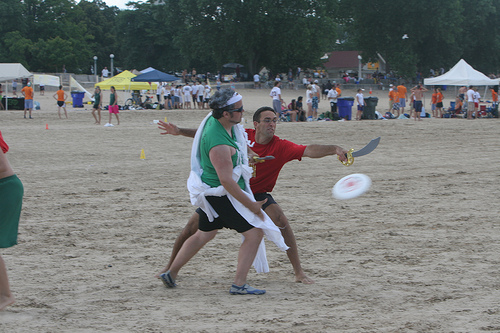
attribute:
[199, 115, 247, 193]
shirt — green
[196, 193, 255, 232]
shorts — black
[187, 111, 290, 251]
toilet paper — white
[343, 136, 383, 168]
knife — fake, man's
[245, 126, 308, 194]
shirt — red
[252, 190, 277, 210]
shorts — black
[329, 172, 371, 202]
frisbee — white, red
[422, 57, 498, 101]
tent — white, large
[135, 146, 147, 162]
cone — yellow, small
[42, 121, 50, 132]
cone — orange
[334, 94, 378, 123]
trash cans — plastic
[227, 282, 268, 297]
shoe — blue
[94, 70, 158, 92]
tent — yellow, large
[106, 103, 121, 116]
shorts — pink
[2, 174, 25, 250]
shorts — green